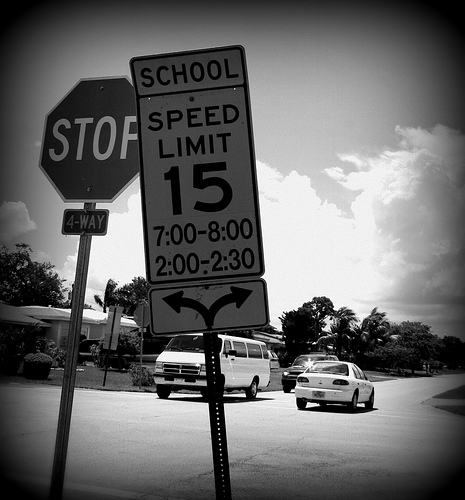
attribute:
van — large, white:
[152, 332, 270, 399]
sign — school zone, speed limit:
[129, 45, 265, 284]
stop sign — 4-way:
[39, 74, 145, 235]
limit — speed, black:
[152, 99, 237, 215]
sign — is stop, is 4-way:
[38, 70, 135, 235]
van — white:
[146, 307, 274, 414]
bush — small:
[21, 352, 52, 379]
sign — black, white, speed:
[113, 30, 289, 342]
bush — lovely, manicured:
[20, 348, 52, 379]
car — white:
[294, 359, 375, 410]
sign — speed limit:
[125, 37, 272, 339]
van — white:
[150, 334, 278, 400]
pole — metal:
[199, 330, 235, 494]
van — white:
[150, 320, 272, 398]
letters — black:
[137, 102, 252, 275]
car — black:
[283, 348, 337, 397]